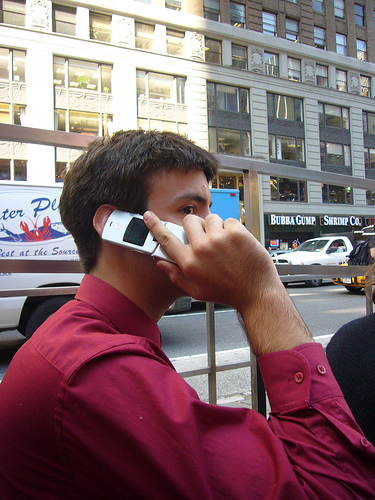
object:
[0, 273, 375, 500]
shirt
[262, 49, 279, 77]
window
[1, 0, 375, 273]
building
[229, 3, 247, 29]
window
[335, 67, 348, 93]
window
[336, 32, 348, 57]
window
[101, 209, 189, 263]
phone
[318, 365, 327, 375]
button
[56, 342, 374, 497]
shirt sleeve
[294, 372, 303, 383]
button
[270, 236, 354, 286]
truck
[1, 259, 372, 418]
road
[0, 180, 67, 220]
lettering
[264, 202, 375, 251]
store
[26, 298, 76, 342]
tire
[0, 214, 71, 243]
lobster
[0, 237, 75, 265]
lettering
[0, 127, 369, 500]
man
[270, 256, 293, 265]
bumper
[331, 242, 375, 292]
car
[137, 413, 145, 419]
speck of dirt